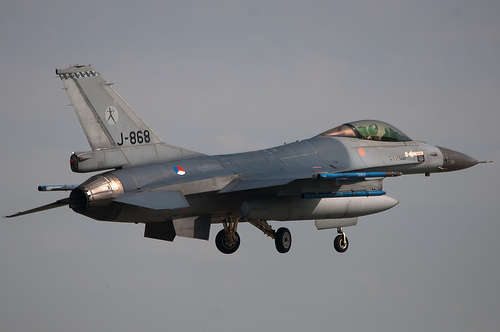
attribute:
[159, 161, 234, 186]
logo — red, white, and blue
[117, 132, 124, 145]
letter — black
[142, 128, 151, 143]
number — black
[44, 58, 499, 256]
plane — gray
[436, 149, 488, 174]
nose — BLACK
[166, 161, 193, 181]
circle — red, blue , white 